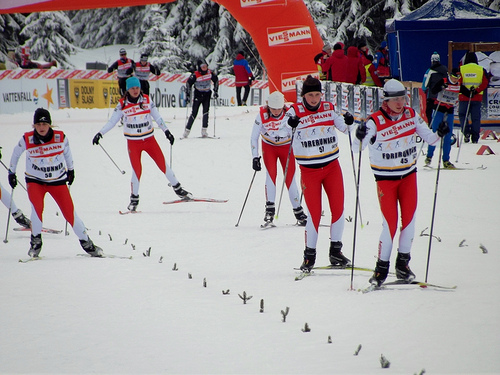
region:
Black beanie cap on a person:
[300, 73, 325, 93]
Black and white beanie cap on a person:
[381, 77, 411, 99]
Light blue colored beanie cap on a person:
[125, 75, 140, 89]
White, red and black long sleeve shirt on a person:
[97, 95, 168, 135]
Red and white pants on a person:
[126, 133, 186, 194]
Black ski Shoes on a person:
[298, 241, 352, 268]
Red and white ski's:
[118, 195, 229, 216]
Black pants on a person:
[185, 91, 212, 130]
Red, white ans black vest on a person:
[191, 69, 213, 91]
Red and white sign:
[0, 0, 335, 103]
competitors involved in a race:
[0, 65, 480, 297]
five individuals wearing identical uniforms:
[6, 75, 422, 269]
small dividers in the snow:
[86, 200, 498, 373]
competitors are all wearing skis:
[0, 73, 479, 301]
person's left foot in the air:
[116, 73, 226, 219]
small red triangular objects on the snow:
[463, 122, 499, 162]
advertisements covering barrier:
[2, 70, 497, 125]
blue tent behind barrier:
[389, 0, 499, 130]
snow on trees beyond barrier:
[4, 0, 357, 65]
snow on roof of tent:
[406, 3, 498, 27]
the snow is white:
[116, 310, 150, 356]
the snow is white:
[108, 294, 210, 373]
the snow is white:
[136, 283, 176, 330]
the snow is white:
[77, 283, 158, 360]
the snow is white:
[151, 319, 193, 345]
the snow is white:
[159, 329, 205, 366]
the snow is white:
[85, 327, 153, 372]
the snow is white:
[100, 251, 234, 359]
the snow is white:
[157, 337, 181, 359]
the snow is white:
[131, 348, 156, 365]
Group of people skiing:
[16, 67, 434, 305]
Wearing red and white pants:
[305, 162, 349, 262]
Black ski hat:
[304, 75, 320, 98]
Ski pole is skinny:
[95, 135, 131, 180]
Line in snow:
[104, 233, 401, 371]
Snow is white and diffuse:
[134, 234, 306, 371]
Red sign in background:
[223, 15, 323, 74]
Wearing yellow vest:
[465, 64, 486, 99]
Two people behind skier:
[117, 33, 160, 82]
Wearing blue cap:
[117, 72, 142, 92]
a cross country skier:
[6, 103, 111, 262]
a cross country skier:
[87, 74, 218, 215]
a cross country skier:
[232, 84, 306, 226]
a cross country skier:
[284, 80, 363, 288]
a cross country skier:
[357, 78, 452, 300]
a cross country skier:
[175, 57, 222, 137]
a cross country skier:
[420, 69, 470, 174]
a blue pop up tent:
[386, 1, 497, 76]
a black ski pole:
[92, 140, 127, 180]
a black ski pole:
[228, 171, 254, 230]